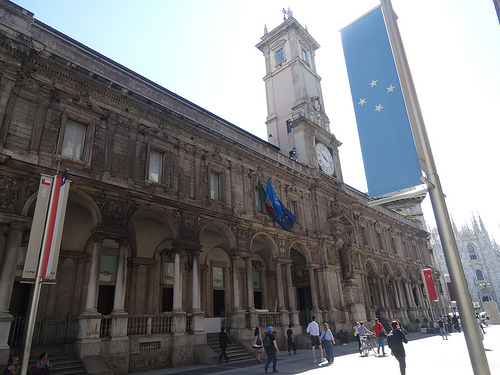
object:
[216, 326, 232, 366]
person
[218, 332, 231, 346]
black shirt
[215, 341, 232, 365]
black pants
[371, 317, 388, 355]
person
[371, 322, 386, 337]
red shirt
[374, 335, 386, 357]
blue jeans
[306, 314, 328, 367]
person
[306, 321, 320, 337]
white shirt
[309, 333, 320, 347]
dark shorts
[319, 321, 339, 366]
person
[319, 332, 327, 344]
bag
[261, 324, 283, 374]
person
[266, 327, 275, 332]
blue hat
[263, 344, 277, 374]
dark pants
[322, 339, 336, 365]
blue pants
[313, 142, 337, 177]
clock face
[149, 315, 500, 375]
sidewalk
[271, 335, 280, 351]
right arm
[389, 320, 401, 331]
head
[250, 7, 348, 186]
clock tower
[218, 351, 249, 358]
steps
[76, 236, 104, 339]
pillar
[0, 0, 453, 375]
building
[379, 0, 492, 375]
pole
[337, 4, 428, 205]
banner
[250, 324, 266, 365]
person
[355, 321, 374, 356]
person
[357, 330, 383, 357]
bicycle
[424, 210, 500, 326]
cathedral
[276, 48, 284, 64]
window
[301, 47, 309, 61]
window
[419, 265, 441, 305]
banner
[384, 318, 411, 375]
people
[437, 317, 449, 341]
people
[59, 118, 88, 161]
window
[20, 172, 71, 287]
banner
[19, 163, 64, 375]
pole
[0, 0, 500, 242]
sky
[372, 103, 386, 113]
stars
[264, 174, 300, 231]
flags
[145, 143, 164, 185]
window